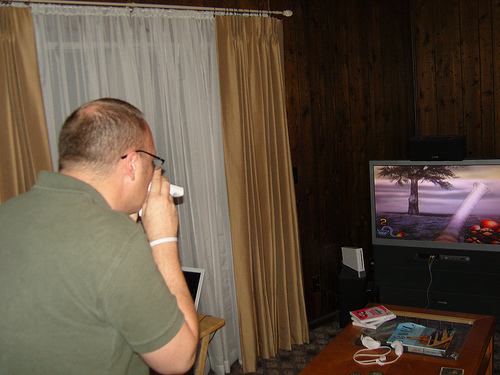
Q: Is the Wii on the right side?
A: Yes, the Wii is on the right of the image.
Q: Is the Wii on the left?
A: No, the Wii is on the right of the image.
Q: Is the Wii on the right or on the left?
A: The Wii is on the right of the image.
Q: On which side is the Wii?
A: The Wii is on the right of the image.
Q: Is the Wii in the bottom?
A: Yes, the Wii is in the bottom of the image.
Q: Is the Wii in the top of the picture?
A: No, the Wii is in the bottom of the image.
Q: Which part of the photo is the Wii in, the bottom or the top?
A: The Wii is in the bottom of the image.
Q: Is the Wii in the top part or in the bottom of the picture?
A: The Wii is in the bottom of the image.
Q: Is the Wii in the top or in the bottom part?
A: The Wii is in the bottom of the image.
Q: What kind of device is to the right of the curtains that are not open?
A: The device is a Wii.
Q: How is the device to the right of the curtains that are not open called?
A: The device is a Wii.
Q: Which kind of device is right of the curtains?
A: The device is a Wii.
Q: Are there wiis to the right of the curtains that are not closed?
A: Yes, there is a Wii to the right of the curtains.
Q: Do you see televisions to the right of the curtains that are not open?
A: No, there is a Wii to the right of the curtains.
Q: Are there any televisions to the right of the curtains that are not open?
A: No, there is a Wii to the right of the curtains.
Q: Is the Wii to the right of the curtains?
A: Yes, the Wii is to the right of the curtains.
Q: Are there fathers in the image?
A: No, there are no fathers.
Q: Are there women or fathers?
A: No, there are no fathers or women.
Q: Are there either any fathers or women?
A: No, there are no fathers or women.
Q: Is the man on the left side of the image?
A: Yes, the man is on the left of the image.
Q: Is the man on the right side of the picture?
A: No, the man is on the left of the image.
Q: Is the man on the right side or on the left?
A: The man is on the left of the image.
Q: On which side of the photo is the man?
A: The man is on the left of the image.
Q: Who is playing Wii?
A: The man is playing wii.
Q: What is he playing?
A: The man is playing wii.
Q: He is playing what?
A: The man is playing wii.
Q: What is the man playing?
A: The man is playing wii.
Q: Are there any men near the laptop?
A: Yes, there is a man near the laptop.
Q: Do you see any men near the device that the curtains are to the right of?
A: Yes, there is a man near the laptop.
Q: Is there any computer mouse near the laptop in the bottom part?
A: No, there is a man near the laptop.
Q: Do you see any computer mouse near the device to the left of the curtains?
A: No, there is a man near the laptop.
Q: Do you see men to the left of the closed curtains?
A: Yes, there is a man to the left of the curtains.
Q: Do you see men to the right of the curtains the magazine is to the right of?
A: No, the man is to the left of the curtains.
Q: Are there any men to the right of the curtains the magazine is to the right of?
A: No, the man is to the left of the curtains.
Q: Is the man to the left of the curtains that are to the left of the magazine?
A: Yes, the man is to the left of the curtains.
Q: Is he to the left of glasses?
A: No, the man is to the left of the curtains.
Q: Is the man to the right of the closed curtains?
A: No, the man is to the left of the curtains.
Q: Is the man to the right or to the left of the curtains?
A: The man is to the left of the curtains.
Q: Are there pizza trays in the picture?
A: No, there are no pizza trays.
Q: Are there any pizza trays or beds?
A: No, there are no pizza trays or beds.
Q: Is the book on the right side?
A: Yes, the book is on the right of the image.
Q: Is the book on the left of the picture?
A: No, the book is on the right of the image.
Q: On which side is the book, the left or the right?
A: The book is on the right of the image.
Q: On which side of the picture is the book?
A: The book is on the right of the image.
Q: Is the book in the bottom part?
A: Yes, the book is in the bottom of the image.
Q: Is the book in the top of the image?
A: No, the book is in the bottom of the image.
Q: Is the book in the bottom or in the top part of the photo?
A: The book is in the bottom of the image.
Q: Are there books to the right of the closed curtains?
A: Yes, there is a book to the right of the curtains.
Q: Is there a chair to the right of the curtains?
A: No, there is a book to the right of the curtains.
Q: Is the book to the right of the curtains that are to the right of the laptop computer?
A: Yes, the book is to the right of the curtains.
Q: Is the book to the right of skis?
A: No, the book is to the right of the curtains.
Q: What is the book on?
A: The book is on the table.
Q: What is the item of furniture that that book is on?
A: The piece of furniture is a table.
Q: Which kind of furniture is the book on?
A: The book is on the table.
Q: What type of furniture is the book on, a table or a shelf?
A: The book is on a table.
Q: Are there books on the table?
A: Yes, there is a book on the table.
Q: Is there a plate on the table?
A: No, there is a book on the table.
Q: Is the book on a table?
A: Yes, the book is on a table.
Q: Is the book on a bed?
A: No, the book is on a table.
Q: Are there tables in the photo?
A: Yes, there is a table.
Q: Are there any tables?
A: Yes, there is a table.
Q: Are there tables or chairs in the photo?
A: Yes, there is a table.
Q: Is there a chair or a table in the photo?
A: Yes, there is a table.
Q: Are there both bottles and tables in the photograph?
A: No, there is a table but no bottles.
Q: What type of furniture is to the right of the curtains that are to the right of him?
A: The piece of furniture is a table.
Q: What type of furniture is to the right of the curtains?
A: The piece of furniture is a table.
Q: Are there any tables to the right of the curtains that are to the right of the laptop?
A: Yes, there is a table to the right of the curtains.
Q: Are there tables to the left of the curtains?
A: No, the table is to the right of the curtains.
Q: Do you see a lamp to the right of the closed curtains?
A: No, there is a table to the right of the curtains.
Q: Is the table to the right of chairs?
A: No, the table is to the right of the curtains.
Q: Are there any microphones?
A: No, there are no microphones.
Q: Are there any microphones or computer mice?
A: No, there are no microphones or computer mice.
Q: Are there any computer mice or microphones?
A: No, there are no microphones or computer mice.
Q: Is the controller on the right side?
A: Yes, the controller is on the right of the image.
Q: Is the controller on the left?
A: No, the controller is on the right of the image.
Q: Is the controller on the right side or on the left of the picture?
A: The controller is on the right of the image.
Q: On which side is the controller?
A: The controller is on the right of the image.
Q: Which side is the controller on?
A: The controller is on the right of the image.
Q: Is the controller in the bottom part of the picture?
A: Yes, the controller is in the bottom of the image.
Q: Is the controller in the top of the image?
A: No, the controller is in the bottom of the image.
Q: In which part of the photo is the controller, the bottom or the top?
A: The controller is in the bottom of the image.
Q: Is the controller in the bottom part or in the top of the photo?
A: The controller is in the bottom of the image.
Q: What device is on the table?
A: The device is a controller.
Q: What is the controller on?
A: The controller is on the table.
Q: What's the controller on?
A: The controller is on the table.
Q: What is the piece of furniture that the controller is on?
A: The piece of furniture is a table.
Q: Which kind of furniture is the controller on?
A: The controller is on the table.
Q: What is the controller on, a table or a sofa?
A: The controller is on a table.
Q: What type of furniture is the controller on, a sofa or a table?
A: The controller is on a table.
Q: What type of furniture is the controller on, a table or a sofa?
A: The controller is on a table.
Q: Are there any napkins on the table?
A: No, there is a controller on the table.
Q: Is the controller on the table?
A: Yes, the controller is on the table.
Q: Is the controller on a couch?
A: No, the controller is on the table.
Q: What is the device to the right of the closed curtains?
A: The device is a controller.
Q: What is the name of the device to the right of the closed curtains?
A: The device is a controller.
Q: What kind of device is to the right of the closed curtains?
A: The device is a controller.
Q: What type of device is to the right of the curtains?
A: The device is a controller.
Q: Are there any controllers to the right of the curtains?
A: Yes, there is a controller to the right of the curtains.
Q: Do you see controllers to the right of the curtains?
A: Yes, there is a controller to the right of the curtains.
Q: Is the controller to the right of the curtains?
A: Yes, the controller is to the right of the curtains.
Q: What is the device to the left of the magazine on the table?
A: The device is a controller.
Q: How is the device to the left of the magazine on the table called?
A: The device is a controller.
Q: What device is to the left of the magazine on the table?
A: The device is a controller.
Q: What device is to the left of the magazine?
A: The device is a controller.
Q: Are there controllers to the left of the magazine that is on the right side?
A: Yes, there is a controller to the left of the magazine.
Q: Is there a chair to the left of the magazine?
A: No, there is a controller to the left of the magazine.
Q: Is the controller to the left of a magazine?
A: Yes, the controller is to the left of a magazine.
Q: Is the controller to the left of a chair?
A: No, the controller is to the left of a magazine.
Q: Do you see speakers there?
A: Yes, there is a speaker.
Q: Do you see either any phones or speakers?
A: Yes, there is a speaker.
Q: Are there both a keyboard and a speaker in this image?
A: No, there is a speaker but no keyboards.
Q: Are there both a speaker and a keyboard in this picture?
A: No, there is a speaker but no keyboards.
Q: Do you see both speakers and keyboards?
A: No, there is a speaker but no keyboards.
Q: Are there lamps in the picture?
A: No, there are no lamps.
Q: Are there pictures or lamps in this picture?
A: No, there are no lamps or pictures.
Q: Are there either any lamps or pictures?
A: No, there are no lamps or pictures.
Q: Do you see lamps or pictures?
A: No, there are no lamps or pictures.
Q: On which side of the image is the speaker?
A: The speaker is on the right of the image.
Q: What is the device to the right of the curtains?
A: The device is a speaker.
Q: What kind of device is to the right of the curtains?
A: The device is a speaker.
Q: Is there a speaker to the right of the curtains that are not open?
A: Yes, there is a speaker to the right of the curtains.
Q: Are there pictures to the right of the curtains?
A: No, there is a speaker to the right of the curtains.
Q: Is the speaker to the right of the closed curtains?
A: Yes, the speaker is to the right of the curtains.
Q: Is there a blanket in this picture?
A: No, there are no blankets.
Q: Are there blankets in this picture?
A: No, there are no blankets.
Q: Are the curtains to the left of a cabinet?
A: No, the curtains are to the left of a speaker.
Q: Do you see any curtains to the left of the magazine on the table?
A: Yes, there are curtains to the left of the magazine.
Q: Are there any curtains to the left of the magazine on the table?
A: Yes, there are curtains to the left of the magazine.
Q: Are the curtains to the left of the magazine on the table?
A: Yes, the curtains are to the left of the magazine.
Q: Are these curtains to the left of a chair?
A: No, the curtains are to the left of the magazine.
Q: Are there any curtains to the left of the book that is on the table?
A: Yes, there are curtains to the left of the book.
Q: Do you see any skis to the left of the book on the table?
A: No, there are curtains to the left of the book.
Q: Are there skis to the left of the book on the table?
A: No, there are curtains to the left of the book.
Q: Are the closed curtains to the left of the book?
A: Yes, the curtains are to the left of the book.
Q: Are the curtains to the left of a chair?
A: No, the curtains are to the left of the book.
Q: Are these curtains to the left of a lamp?
A: No, the curtains are to the left of the table.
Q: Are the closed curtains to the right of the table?
A: No, the curtains are to the left of the table.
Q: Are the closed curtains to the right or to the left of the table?
A: The curtains are to the left of the table.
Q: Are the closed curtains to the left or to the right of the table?
A: The curtains are to the left of the table.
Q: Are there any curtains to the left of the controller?
A: Yes, there are curtains to the left of the controller.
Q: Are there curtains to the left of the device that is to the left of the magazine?
A: Yes, there are curtains to the left of the controller.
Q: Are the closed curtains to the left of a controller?
A: Yes, the curtains are to the left of a controller.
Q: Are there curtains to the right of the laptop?
A: Yes, there are curtains to the right of the laptop.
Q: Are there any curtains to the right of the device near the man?
A: Yes, there are curtains to the right of the laptop.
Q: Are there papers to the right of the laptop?
A: No, there are curtains to the right of the laptop.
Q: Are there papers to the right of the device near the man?
A: No, there are curtains to the right of the laptop.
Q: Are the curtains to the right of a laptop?
A: Yes, the curtains are to the right of a laptop.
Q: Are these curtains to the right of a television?
A: No, the curtains are to the right of a laptop.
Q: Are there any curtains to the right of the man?
A: Yes, there are curtains to the right of the man.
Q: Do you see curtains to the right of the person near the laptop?
A: Yes, there are curtains to the right of the man.